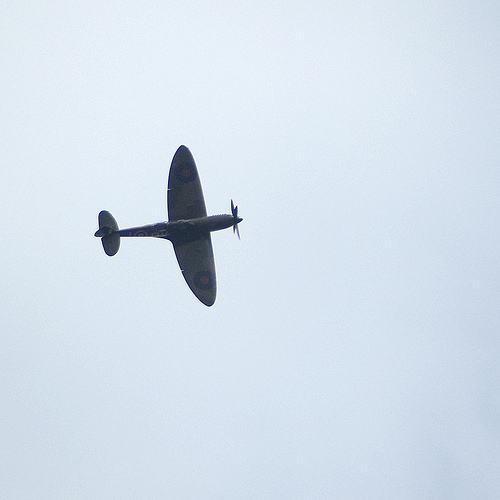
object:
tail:
[94, 209, 122, 257]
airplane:
[93, 143, 241, 306]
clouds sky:
[254, 253, 444, 407]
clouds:
[26, 31, 111, 95]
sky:
[0, 0, 500, 500]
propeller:
[230, 199, 244, 240]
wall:
[169, 108, 254, 142]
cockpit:
[155, 219, 191, 240]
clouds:
[424, 6, 500, 33]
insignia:
[193, 268, 214, 290]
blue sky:
[0, 0, 118, 69]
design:
[193, 270, 214, 291]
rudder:
[94, 229, 103, 237]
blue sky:
[358, 107, 473, 264]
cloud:
[400, 337, 417, 356]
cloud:
[115, 320, 161, 356]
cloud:
[336, 205, 388, 238]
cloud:
[180, 419, 321, 463]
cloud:
[224, 317, 271, 385]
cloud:
[274, 115, 378, 165]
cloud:
[228, 425, 288, 471]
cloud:
[320, 23, 341, 43]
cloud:
[27, 454, 75, 496]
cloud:
[344, 361, 457, 452]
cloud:
[64, 260, 95, 290]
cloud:
[303, 245, 356, 282]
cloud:
[266, 187, 291, 221]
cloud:
[338, 297, 424, 347]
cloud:
[333, 404, 385, 456]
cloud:
[114, 390, 141, 438]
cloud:
[401, 481, 478, 500]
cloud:
[192, 467, 234, 500]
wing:
[173, 233, 218, 308]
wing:
[167, 143, 209, 223]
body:
[94, 198, 242, 257]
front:
[217, 197, 244, 241]